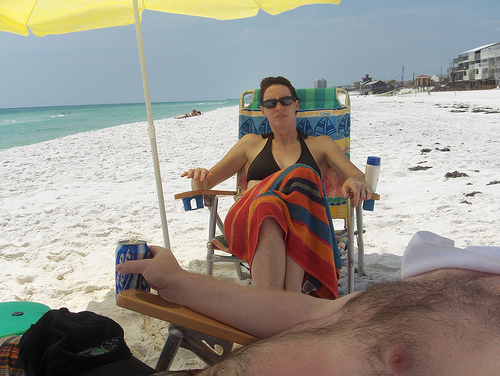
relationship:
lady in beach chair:
[181, 76, 372, 293] [178, 81, 379, 275]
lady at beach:
[181, 76, 372, 293] [24, 107, 179, 229]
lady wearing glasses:
[181, 76, 372, 293] [261, 93, 299, 110]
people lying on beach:
[173, 107, 205, 122] [0, 87, 500, 367]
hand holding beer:
[95, 234, 237, 336] [117, 239, 164, 304]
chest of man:
[186, 258, 495, 374] [99, 238, 499, 373]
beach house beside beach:
[432, 42, 500, 91] [0, 87, 500, 367]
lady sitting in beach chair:
[181, 76, 372, 293] [175, 83, 383, 294]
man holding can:
[0, 243, 498, 373] [61, 188, 181, 342]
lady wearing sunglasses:
[181, 76, 372, 293] [261, 95, 300, 108]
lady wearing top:
[181, 76, 372, 293] [243, 126, 323, 182]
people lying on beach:
[173, 107, 207, 122] [2, 110, 499, 305]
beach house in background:
[440, 49, 490, 98] [284, 35, 498, 86]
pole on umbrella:
[107, 24, 222, 270] [121, 36, 197, 261]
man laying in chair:
[0, 243, 498, 373] [115, 285, 265, 368]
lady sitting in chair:
[181, 76, 372, 293] [175, 87, 363, 297]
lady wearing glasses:
[181, 76, 372, 293] [251, 83, 306, 131]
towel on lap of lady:
[221, 169, 359, 254] [201, 70, 359, 247]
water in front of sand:
[0, 96, 236, 150] [2, 81, 497, 372]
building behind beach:
[408, 70, 438, 89] [26, 62, 496, 348]